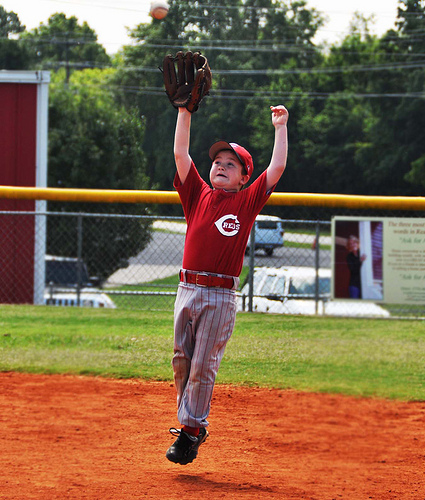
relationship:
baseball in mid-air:
[143, 4, 176, 23] [2, 1, 423, 41]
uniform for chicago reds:
[166, 156, 273, 284] [210, 212, 250, 240]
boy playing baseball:
[147, 72, 301, 466] [143, 4, 176, 23]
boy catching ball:
[147, 72, 301, 466] [143, 4, 176, 23]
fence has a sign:
[0, 210, 425, 321] [324, 207, 423, 306]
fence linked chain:
[0, 210, 425, 321] [251, 220, 330, 307]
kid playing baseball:
[147, 72, 301, 466] [143, 4, 176, 23]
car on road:
[244, 210, 287, 257] [239, 235, 331, 267]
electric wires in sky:
[1, 0, 424, 106] [2, 1, 423, 41]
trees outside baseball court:
[1, 0, 424, 106] [1, 309, 424, 496]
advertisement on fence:
[324, 207, 423, 306] [0, 210, 425, 321]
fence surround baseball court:
[2, 203, 177, 301] [1, 309, 424, 496]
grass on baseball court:
[5, 294, 172, 371] [1, 309, 424, 496]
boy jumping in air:
[147, 72, 301, 466] [1, 0, 424, 106]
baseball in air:
[143, 4, 176, 23] [1, 0, 424, 106]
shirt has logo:
[166, 156, 273, 284] [210, 212, 250, 240]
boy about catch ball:
[147, 72, 301, 466] [143, 4, 176, 23]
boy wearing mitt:
[147, 72, 301, 466] [152, 48, 222, 115]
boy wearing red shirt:
[147, 72, 301, 466] [166, 156, 273, 284]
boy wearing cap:
[147, 72, 301, 466] [200, 137, 259, 178]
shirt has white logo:
[166, 156, 273, 284] [210, 212, 250, 240]